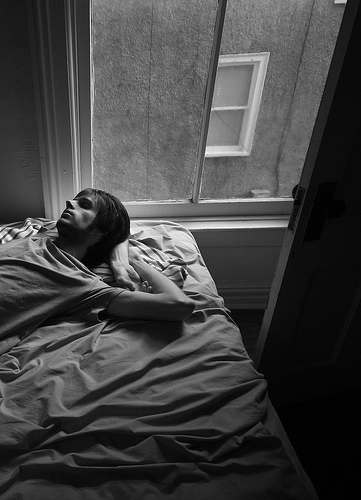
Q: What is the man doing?
A: Sleeping.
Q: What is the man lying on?
A: A bed.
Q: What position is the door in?
A: Open.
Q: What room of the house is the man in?
A: The bedroom.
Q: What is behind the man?
A: A window.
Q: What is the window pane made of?
A: Glass.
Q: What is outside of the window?
A: A building with another window.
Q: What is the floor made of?
A: Hardwood.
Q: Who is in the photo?
A: A guy.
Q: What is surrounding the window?
A: A white frame.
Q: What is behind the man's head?
A: Arm.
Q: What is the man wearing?
A: A shirt.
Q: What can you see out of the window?
A: A window on a building.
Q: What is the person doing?
A: Laying on the bed.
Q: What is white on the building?
A: A window.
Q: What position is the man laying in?
A: On his back.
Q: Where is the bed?
A: In a room.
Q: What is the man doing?
A: Lying down.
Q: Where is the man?
A: On the bed.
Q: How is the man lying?
A: On his back.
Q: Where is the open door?
A: On the right from the bed.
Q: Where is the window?
A: Behind the bed.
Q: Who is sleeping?
A: The man.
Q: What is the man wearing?
A: A t-shirt.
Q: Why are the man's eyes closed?
A: He is sleeping.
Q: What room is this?
A: Bedroom.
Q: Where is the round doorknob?
A: On the door.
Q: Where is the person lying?
A: On the bed.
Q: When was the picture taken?
A: Daytime.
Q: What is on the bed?
A: A bed sheet.